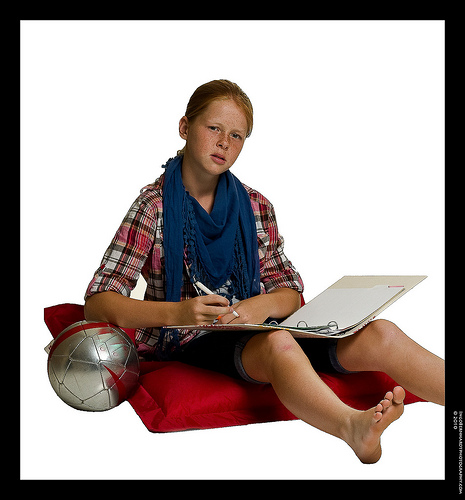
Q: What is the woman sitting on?
A: A red pillow.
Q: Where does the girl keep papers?
A: In a binder.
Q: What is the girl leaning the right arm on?
A: A soccer ball.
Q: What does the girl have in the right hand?
A: A pen.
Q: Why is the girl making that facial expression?
A: Because the girl is deep in thought.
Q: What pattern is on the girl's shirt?
A: Flannel.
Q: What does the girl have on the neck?
A: A blue scarf.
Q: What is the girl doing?
A: Homework.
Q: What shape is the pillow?
A: Square.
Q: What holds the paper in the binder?
A: Three metal rings.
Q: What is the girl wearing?
A: Girl wearing plaid shirt.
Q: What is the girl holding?
A: Ivory binder file folder.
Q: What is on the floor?
A: Red cushioned floor mat.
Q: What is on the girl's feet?
A: Girl not wearing shoes.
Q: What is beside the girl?
A: Silver colored sports ball.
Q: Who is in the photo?
A: Teenage girl with red hair.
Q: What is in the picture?
A: Teenage girl wearing plaid shirt with blue scarf around neck.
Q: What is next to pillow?
A: Soccer ball.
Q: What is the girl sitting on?
A: Pillow.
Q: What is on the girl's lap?
A: Notebook.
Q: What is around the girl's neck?
A: Scarf.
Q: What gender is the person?
A: Female.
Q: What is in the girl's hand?
A: Pen.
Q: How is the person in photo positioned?
A: Sitting.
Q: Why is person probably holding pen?
A: Writing.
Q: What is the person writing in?
A: Notebook.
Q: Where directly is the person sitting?
A: On cushion.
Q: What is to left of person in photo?
A: Soccer ball.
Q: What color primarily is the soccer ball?
A: Silver.